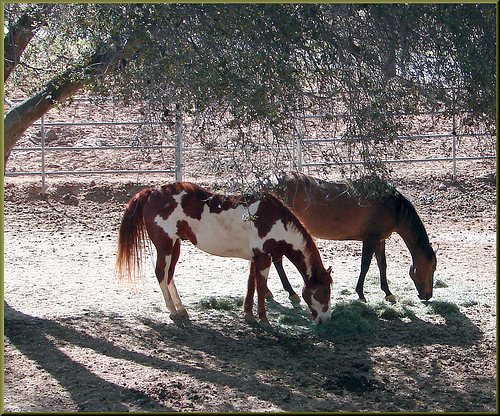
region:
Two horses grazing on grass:
[120, 176, 445, 338]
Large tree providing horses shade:
[0, 0, 483, 204]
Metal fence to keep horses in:
[19, 100, 496, 169]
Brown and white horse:
[117, 186, 334, 326]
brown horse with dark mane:
[256, 175, 449, 302]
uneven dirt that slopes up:
[0, 171, 498, 233]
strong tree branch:
[2, 35, 178, 151]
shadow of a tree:
[21, 309, 298, 407]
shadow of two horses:
[163, 297, 498, 380]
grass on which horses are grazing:
[203, 282, 398, 347]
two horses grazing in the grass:
[92, 169, 459, 341]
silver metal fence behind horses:
[44, 80, 484, 170]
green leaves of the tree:
[74, 16, 492, 117]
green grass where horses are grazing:
[267, 294, 477, 341]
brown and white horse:
[111, 177, 340, 337]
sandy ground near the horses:
[2, 205, 105, 312]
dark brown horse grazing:
[317, 166, 457, 310]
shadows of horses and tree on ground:
[5, 325, 492, 410]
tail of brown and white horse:
[108, 186, 150, 275]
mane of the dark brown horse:
[407, 197, 446, 260]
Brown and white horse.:
[112, 178, 337, 331]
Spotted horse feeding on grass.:
[116, 181, 335, 340]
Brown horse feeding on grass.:
[264, 171, 439, 306]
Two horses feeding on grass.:
[113, 168, 438, 333]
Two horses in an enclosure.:
[113, 168, 439, 332]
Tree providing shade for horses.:
[1, 1, 498, 178]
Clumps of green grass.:
[203, 291, 488, 346]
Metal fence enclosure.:
[32, 87, 499, 199]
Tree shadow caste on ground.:
[6, 300, 498, 415]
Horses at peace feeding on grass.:
[112, 171, 438, 327]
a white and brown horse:
[102, 179, 337, 342]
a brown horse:
[215, 162, 457, 314]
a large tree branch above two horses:
[12, 12, 448, 137]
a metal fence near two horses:
[7, 81, 492, 182]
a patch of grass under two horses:
[27, 222, 466, 324]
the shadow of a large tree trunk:
[15, 297, 253, 414]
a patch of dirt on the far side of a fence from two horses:
[37, 52, 487, 155]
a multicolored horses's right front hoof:
[251, 311, 281, 345]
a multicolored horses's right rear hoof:
[162, 307, 178, 325]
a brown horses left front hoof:
[384, 288, 395, 306]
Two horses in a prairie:
[103, 149, 465, 336]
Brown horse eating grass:
[245, 165, 445, 322]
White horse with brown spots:
[113, 173, 335, 329]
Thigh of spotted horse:
[146, 198, 176, 243]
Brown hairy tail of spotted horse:
[111, 180, 163, 280]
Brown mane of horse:
[268, 192, 325, 267]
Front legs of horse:
[238, 252, 280, 339]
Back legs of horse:
[145, 242, 203, 331]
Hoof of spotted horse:
[163, 307, 195, 330]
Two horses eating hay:
[104, 155, 450, 341]